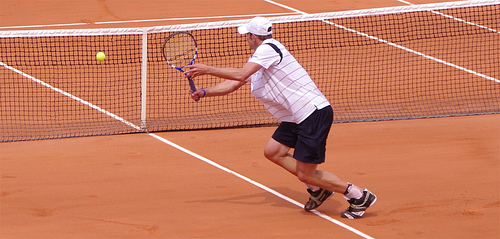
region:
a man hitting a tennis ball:
[156, 13, 407, 224]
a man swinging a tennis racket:
[166, 15, 402, 224]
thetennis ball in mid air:
[85, 44, 121, 71]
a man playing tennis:
[152, 9, 427, 226]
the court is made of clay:
[396, 122, 496, 227]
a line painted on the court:
[153, 133, 280, 207]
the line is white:
[148, 125, 254, 214]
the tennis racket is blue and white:
[158, 27, 209, 99]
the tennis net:
[369, 16, 485, 118]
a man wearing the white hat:
[191, 0, 439, 237]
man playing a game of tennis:
[84, 14, 393, 224]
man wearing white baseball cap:
[227, 14, 271, 51]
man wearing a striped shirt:
[240, 15, 332, 130]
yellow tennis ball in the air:
[78, 47, 113, 67]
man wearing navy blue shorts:
[232, 12, 394, 217]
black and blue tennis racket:
[160, 27, 213, 108]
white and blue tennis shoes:
[335, 188, 377, 223]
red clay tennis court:
[25, 152, 499, 224]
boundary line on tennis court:
[147, 130, 247, 190]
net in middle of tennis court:
[359, 4, 493, 114]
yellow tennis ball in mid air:
[87, 45, 109, 69]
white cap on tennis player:
[226, 11, 281, 46]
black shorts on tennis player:
[265, 98, 335, 165]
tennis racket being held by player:
[152, 23, 215, 113]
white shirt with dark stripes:
[224, 38, 342, 125]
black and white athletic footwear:
[293, 177, 393, 223]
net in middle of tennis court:
[16, 35, 493, 124]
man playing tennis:
[153, 6, 385, 220]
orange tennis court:
[69, 142, 251, 227]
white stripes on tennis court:
[131, 129, 358, 237]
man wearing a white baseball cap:
[235, 14, 275, 36]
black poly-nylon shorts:
[269, 104, 334, 165]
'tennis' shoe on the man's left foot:
[339, 189, 377, 221]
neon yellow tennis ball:
[93, 49, 107, 62]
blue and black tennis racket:
[160, 27, 200, 92]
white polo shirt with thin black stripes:
[246, 37, 332, 126]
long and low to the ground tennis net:
[0, 0, 498, 142]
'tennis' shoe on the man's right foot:
[303, 184, 331, 210]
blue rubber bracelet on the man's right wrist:
[200, 85, 208, 99]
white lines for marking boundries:
[143, 129, 378, 236]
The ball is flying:
[92, 40, 122, 65]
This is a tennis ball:
[62, 38, 129, 81]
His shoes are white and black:
[282, 165, 386, 224]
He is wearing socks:
[329, 175, 389, 222]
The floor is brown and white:
[37, 145, 396, 235]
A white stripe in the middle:
[134, 121, 376, 236]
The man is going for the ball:
[146, 11, 401, 219]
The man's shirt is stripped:
[223, 26, 363, 129]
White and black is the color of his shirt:
[238, 37, 340, 139]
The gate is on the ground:
[4, 80, 218, 155]